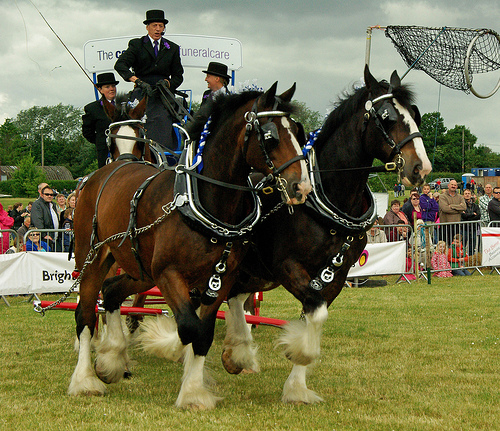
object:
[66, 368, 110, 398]
hooves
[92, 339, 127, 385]
hooves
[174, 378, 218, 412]
hooves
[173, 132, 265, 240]
bridle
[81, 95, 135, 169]
suit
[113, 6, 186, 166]
man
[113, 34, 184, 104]
suit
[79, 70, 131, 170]
person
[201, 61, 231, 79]
hat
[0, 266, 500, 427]
grass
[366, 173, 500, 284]
crowd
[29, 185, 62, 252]
man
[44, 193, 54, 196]
sunglasses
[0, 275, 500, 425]
field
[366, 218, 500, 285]
silver fence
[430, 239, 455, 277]
children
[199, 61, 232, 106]
men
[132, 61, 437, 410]
clydesdale horses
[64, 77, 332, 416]
clydesdale horse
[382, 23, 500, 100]
cone/shaped net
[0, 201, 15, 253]
people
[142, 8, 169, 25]
top hat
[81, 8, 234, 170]
three men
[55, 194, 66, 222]
people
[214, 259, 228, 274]
bells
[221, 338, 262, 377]
white hooves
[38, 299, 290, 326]
red bars